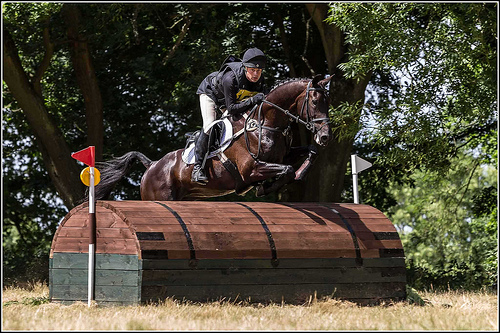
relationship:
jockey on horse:
[189, 44, 269, 186] [77, 72, 334, 206]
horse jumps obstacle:
[77, 72, 334, 206] [45, 196, 412, 308]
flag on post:
[70, 143, 97, 166] [88, 168, 99, 309]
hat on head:
[242, 46, 268, 71] [243, 57, 265, 83]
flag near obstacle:
[70, 143, 97, 166] [45, 196, 412, 308]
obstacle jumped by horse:
[45, 196, 412, 308] [77, 72, 334, 206]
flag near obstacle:
[351, 152, 373, 175] [45, 196, 412, 308]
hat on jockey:
[242, 46, 268, 71] [189, 44, 269, 186]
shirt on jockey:
[195, 53, 269, 117] [189, 44, 269, 186]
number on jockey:
[233, 87, 258, 103] [189, 44, 269, 186]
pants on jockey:
[198, 93, 217, 137] [189, 44, 269, 186]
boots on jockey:
[192, 129, 213, 188] [189, 44, 269, 186]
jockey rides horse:
[189, 44, 269, 186] [77, 72, 334, 206]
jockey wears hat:
[189, 44, 269, 186] [242, 46, 268, 71]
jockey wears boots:
[189, 44, 269, 186] [192, 129, 213, 188]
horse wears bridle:
[77, 72, 334, 206] [243, 96, 311, 162]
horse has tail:
[77, 72, 334, 206] [73, 147, 154, 206]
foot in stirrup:
[191, 164, 211, 185] [195, 166, 210, 188]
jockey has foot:
[189, 44, 269, 186] [191, 164, 211, 185]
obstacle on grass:
[45, 196, 412, 308] [2, 275, 499, 331]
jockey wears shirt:
[189, 44, 269, 186] [195, 53, 269, 117]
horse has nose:
[77, 72, 334, 206] [310, 121, 334, 149]